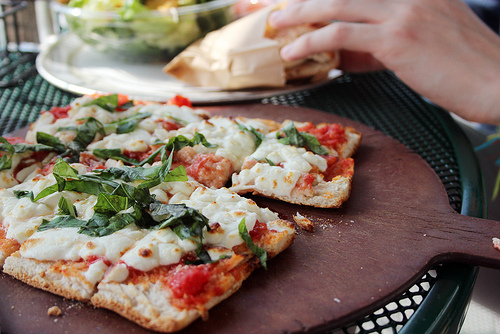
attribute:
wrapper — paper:
[156, 8, 295, 88]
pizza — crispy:
[33, 71, 367, 322]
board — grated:
[142, 103, 479, 294]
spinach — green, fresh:
[24, 159, 161, 236]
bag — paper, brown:
[173, 6, 341, 88]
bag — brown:
[165, 6, 333, 85]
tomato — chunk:
[160, 260, 212, 310]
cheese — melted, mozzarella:
[17, 225, 196, 284]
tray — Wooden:
[1, 97, 496, 332]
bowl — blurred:
[49, 2, 241, 61]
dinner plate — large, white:
[28, 35, 361, 107]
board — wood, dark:
[2, 98, 498, 332]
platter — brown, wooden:
[307, 204, 447, 296]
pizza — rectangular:
[10, 84, 367, 331]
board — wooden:
[14, 100, 482, 322]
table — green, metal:
[5, 28, 468, 328]